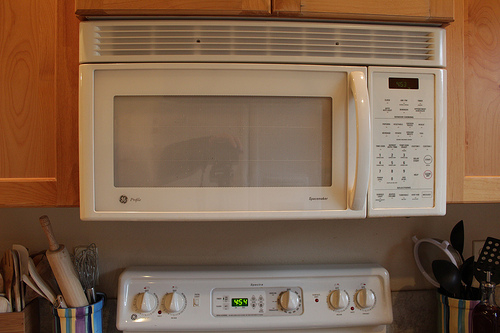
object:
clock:
[389, 78, 420, 90]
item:
[430, 260, 465, 299]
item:
[478, 235, 500, 281]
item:
[1, 249, 15, 312]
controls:
[388, 153, 396, 158]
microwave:
[77, 16, 448, 222]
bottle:
[470, 280, 499, 333]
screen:
[113, 95, 334, 189]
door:
[78, 63, 371, 220]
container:
[52, 290, 104, 332]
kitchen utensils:
[39, 215, 89, 307]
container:
[436, 286, 482, 332]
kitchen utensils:
[409, 236, 464, 290]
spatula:
[28, 254, 59, 305]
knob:
[279, 290, 300, 312]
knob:
[329, 290, 348, 309]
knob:
[162, 291, 187, 313]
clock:
[231, 297, 250, 307]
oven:
[114, 266, 394, 332]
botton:
[423, 155, 433, 165]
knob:
[357, 289, 375, 309]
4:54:
[234, 299, 248, 306]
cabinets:
[443, 0, 498, 209]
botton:
[423, 170, 433, 180]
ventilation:
[88, 20, 440, 67]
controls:
[135, 291, 159, 313]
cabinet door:
[2, 2, 79, 208]